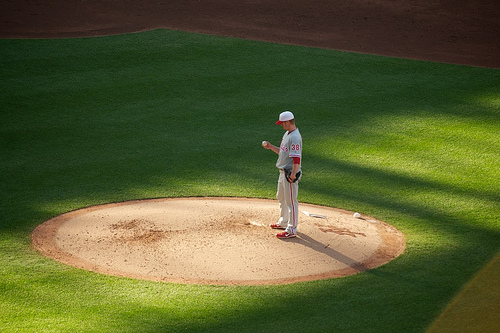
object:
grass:
[0, 27, 499, 333]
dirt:
[0, 0, 500, 71]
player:
[263, 111, 302, 239]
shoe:
[275, 231, 296, 238]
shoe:
[269, 223, 286, 229]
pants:
[276, 169, 302, 235]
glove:
[283, 168, 301, 183]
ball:
[262, 141, 268, 147]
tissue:
[353, 212, 360, 218]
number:
[292, 144, 300, 150]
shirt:
[275, 128, 302, 173]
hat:
[275, 111, 294, 125]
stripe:
[290, 183, 295, 235]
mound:
[29, 195, 407, 287]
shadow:
[2, 2, 500, 332]